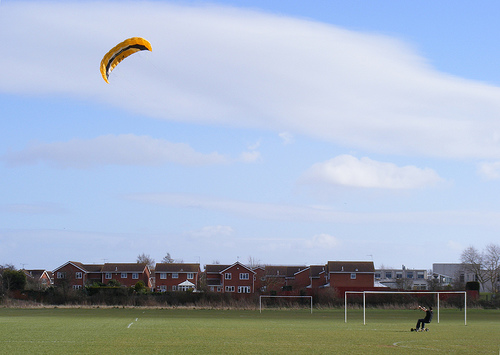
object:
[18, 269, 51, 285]
roof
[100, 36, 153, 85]
kite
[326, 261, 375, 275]
roof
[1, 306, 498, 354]
field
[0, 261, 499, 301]
houses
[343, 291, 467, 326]
poles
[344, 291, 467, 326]
bars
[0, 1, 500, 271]
sky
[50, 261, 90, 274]
roof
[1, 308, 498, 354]
grass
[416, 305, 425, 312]
arms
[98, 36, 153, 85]
sail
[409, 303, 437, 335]
guy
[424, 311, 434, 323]
top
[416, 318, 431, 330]
pants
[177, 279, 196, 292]
gazebo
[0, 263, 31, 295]
trees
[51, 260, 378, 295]
building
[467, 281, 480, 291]
opening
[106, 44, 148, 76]
stripe